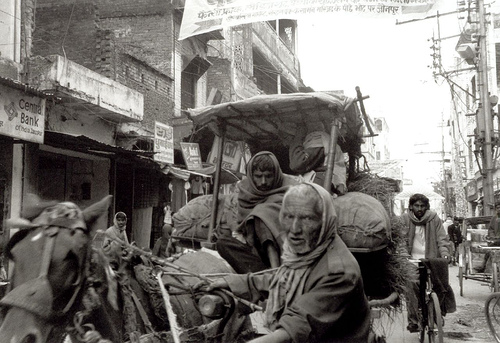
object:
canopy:
[182, 89, 382, 143]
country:
[0, 0, 500, 341]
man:
[394, 192, 452, 331]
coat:
[394, 211, 453, 269]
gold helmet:
[2, 195, 108, 343]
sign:
[178, 138, 203, 170]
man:
[447, 215, 467, 266]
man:
[231, 150, 311, 273]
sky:
[296, 0, 500, 155]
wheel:
[420, 287, 449, 342]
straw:
[343, 170, 402, 201]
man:
[101, 210, 136, 250]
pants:
[408, 260, 455, 323]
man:
[191, 180, 369, 342]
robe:
[278, 178, 337, 269]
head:
[276, 181, 337, 258]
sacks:
[332, 189, 397, 253]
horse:
[0, 191, 256, 342]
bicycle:
[400, 256, 455, 342]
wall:
[0, 140, 115, 280]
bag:
[168, 193, 230, 243]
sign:
[1, 83, 53, 146]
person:
[278, 116, 348, 198]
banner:
[171, 0, 441, 43]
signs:
[149, 119, 179, 167]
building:
[1, 0, 313, 297]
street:
[372, 267, 497, 342]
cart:
[0, 89, 421, 342]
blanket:
[231, 148, 311, 255]